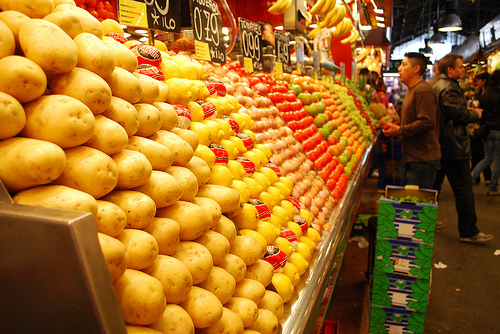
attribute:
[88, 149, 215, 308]
potato — yellow, golden, golden yellow, gold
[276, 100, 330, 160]
tomatoes — red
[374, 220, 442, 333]
boxes — green, cardboard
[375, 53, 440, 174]
man — looking, standing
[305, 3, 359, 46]
bananas — hanging, yellow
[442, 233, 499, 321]
ground — brown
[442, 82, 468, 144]
coat — black, leather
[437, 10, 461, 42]
lamp — circular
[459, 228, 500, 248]
shoes — gray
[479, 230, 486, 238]
shoelaces — white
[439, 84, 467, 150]
jacket — black, leather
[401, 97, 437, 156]
shirt — brown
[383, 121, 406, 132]
pepper — red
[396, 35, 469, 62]
lights — dark, three, hanging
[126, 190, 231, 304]
potatoes — white, stacked, arranged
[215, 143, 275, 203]
lemons — stacked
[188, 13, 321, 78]
signs — prices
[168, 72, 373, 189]
vegetables — food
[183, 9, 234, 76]
board — .79